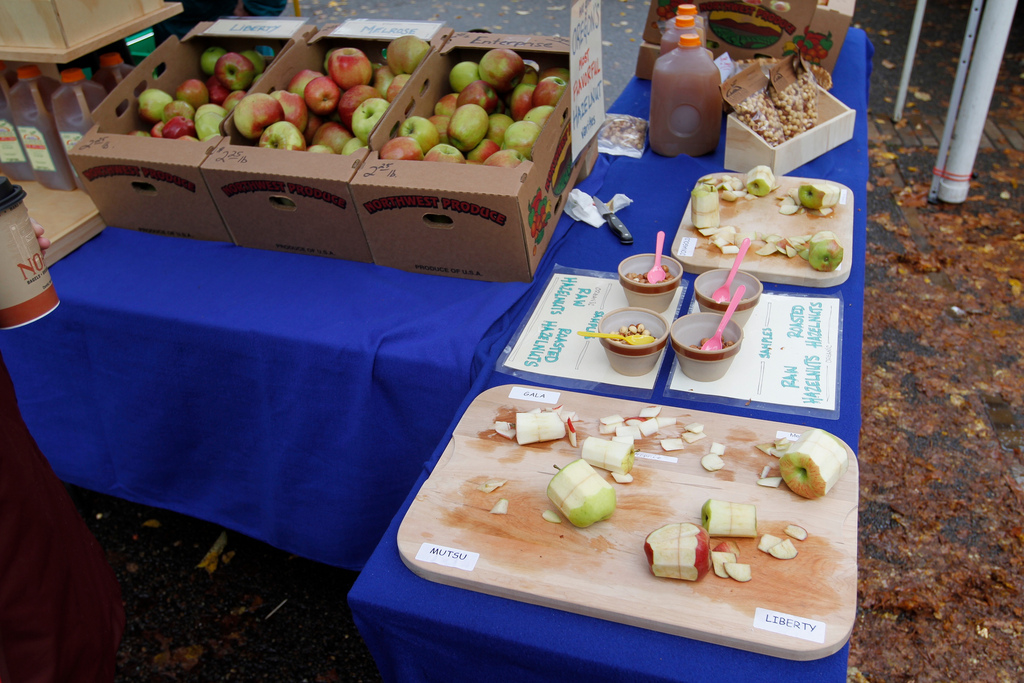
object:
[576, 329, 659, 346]
spoon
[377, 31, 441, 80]
apples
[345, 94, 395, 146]
apples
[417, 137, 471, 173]
apple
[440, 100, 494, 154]
apple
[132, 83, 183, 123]
apple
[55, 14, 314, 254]
box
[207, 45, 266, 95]
apple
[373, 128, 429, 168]
apple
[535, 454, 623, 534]
apple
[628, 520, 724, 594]
apple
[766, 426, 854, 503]
apples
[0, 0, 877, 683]
cloth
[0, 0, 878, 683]
table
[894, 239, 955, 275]
leaves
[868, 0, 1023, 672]
ground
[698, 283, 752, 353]
spoon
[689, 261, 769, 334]
bowl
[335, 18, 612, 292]
box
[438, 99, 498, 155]
apples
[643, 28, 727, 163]
jug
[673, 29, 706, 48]
lid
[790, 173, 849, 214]
apples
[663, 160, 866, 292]
cutting board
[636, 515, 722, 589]
apple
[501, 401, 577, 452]
apple core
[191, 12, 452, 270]
boxes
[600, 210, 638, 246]
handle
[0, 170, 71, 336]
cup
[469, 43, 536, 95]
apples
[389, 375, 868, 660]
board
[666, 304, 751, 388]
bowl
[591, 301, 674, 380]
bowl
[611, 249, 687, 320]
bowl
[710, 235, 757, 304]
spoon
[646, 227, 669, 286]
spoon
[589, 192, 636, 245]
knife